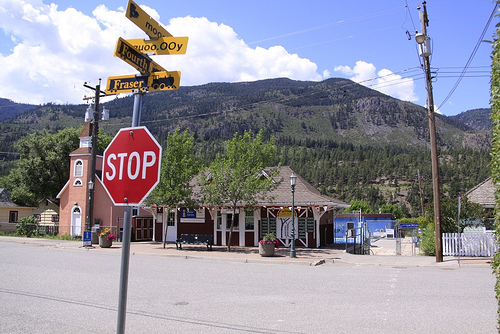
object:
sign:
[101, 125, 163, 206]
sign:
[124, 0, 173, 39]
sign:
[125, 36, 190, 55]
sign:
[114, 36, 168, 74]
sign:
[106, 70, 182, 95]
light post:
[289, 186, 296, 258]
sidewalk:
[0, 235, 326, 266]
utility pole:
[417, 11, 443, 263]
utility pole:
[83, 85, 100, 247]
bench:
[174, 235, 214, 251]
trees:
[194, 128, 284, 251]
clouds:
[351, 59, 379, 76]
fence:
[439, 232, 500, 258]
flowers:
[106, 231, 108, 232]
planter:
[98, 237, 112, 247]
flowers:
[273, 242, 276, 245]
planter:
[259, 243, 275, 256]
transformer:
[418, 36, 432, 57]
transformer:
[86, 108, 94, 120]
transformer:
[101, 109, 109, 121]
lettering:
[105, 151, 157, 181]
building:
[334, 211, 396, 239]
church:
[55, 122, 155, 241]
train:
[151, 74, 175, 89]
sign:
[276, 216, 298, 240]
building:
[142, 166, 350, 248]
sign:
[179, 207, 205, 223]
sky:
[0, 0, 500, 117]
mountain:
[194, 96, 492, 147]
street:
[1, 235, 500, 334]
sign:
[82, 230, 91, 246]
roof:
[152, 165, 351, 207]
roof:
[455, 175, 496, 205]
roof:
[0, 188, 59, 208]